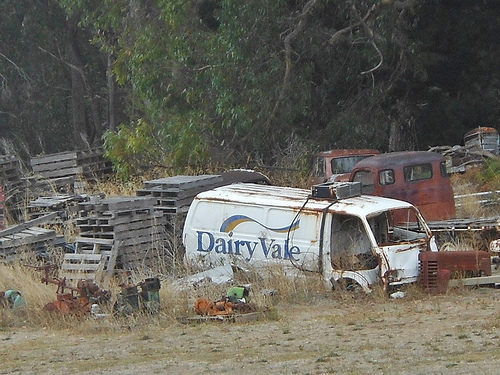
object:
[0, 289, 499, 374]
passage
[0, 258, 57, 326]
grass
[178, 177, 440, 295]
neglected car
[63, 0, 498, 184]
vegetation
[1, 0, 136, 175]
vegetation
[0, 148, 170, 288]
heaped parts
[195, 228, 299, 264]
brand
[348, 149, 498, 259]
brown truck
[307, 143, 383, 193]
brown truck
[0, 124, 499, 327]
dumpsite